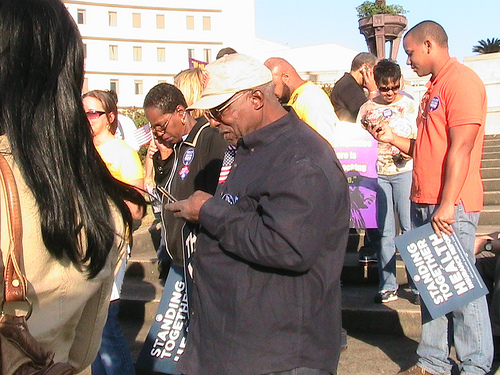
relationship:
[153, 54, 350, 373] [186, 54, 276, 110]
old man with white hat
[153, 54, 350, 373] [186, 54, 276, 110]
old man in white hat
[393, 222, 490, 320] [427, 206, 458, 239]
blue sign in hand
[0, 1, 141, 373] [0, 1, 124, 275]
long haired woman with black hair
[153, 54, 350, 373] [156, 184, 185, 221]
old man with phone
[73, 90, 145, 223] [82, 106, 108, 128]
woman wearing sunglasses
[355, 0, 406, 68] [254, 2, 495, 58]
statue near sky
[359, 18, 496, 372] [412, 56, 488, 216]
man wearing shirt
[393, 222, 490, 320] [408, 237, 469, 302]
blue sign has white writing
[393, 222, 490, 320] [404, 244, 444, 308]
blue sign reads standing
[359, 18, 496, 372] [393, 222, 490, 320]
man holding blue sign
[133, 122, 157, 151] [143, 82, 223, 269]
american flag near lady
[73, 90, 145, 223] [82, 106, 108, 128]
woman has sunglasses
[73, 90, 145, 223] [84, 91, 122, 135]
woman has brown hair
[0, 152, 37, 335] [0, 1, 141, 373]
brown strap with long haired woman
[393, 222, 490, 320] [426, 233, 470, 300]
blue sign reads health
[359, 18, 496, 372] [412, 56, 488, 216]
man in shirt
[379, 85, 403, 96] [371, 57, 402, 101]
dark sunglasses on face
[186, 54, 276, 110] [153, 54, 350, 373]
white hat on old man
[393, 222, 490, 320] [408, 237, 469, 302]
blue sign with white writing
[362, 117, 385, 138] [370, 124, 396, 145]
cell phone in hand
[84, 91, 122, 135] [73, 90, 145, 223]
brown hair on woman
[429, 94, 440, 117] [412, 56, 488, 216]
button on shirt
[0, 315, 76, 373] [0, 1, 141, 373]
purse on long haired woman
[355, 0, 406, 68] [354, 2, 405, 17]
statue holding plant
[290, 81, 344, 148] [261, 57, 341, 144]
yellow shirt on bald man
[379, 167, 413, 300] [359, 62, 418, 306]
jeans on female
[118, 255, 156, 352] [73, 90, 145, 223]
shadow near woman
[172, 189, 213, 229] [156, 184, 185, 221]
hand holding phone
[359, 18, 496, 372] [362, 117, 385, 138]
man holding cell phone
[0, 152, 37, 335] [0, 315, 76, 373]
brown strap near purse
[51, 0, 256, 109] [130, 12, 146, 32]
building has window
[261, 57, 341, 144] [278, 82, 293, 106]
bald man has beard